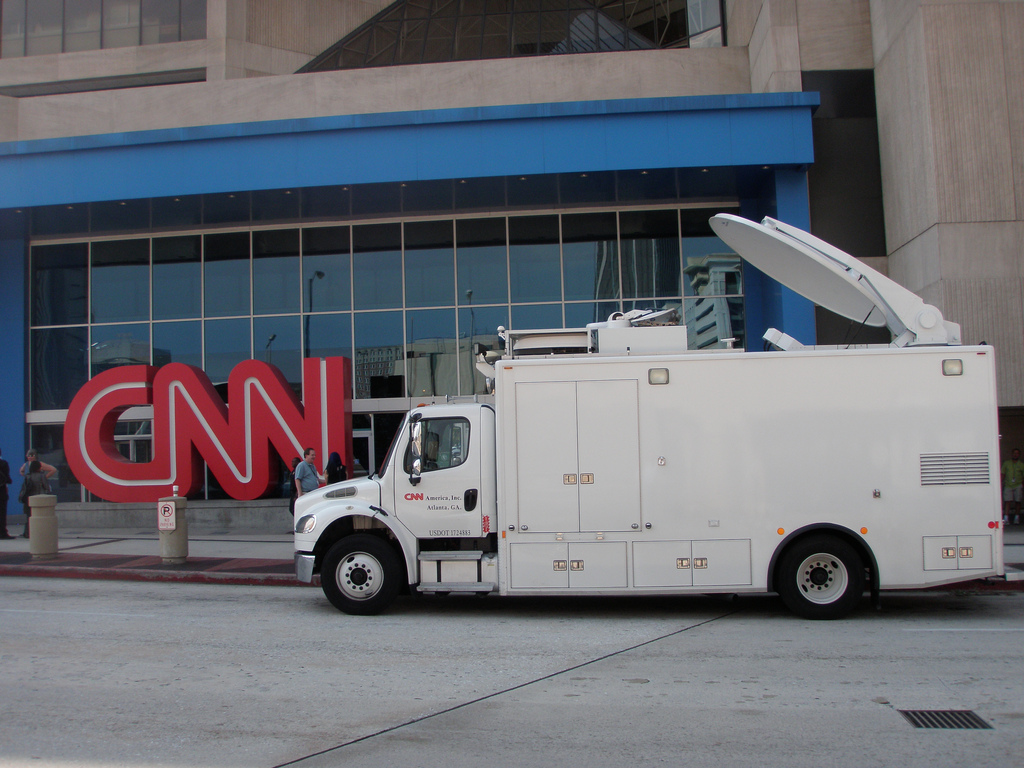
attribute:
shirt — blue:
[288, 467, 317, 496]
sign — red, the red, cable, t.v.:
[52, 344, 353, 513]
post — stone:
[22, 485, 62, 552]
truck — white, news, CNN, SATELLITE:
[273, 182, 993, 608]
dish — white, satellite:
[701, 195, 974, 336]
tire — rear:
[770, 534, 874, 615]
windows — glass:
[26, 195, 753, 502]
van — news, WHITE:
[286, 191, 993, 617]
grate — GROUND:
[889, 696, 993, 735]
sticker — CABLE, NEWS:
[394, 487, 485, 516]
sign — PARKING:
[147, 493, 180, 537]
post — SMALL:
[20, 484, 60, 552]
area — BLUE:
[14, 104, 810, 502]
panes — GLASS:
[27, 201, 747, 493]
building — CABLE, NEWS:
[13, 22, 994, 524]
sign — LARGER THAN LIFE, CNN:
[57, 348, 369, 500]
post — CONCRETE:
[22, 487, 64, 544]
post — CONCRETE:
[145, 485, 200, 552]